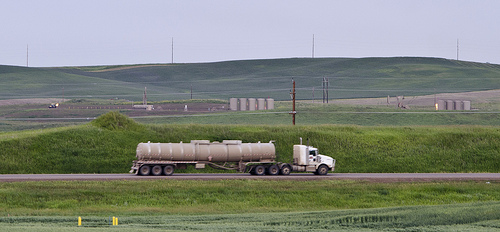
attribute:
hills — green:
[3, 55, 488, 97]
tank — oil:
[132, 136, 278, 168]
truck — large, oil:
[126, 134, 337, 179]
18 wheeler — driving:
[114, 123, 352, 190]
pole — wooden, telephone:
[291, 78, 294, 129]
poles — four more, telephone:
[6, 16, 497, 82]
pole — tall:
[308, 30, 315, 57]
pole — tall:
[454, 37, 460, 60]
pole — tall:
[169, 35, 174, 63]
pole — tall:
[24, 42, 31, 67]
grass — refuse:
[95, 182, 445, 230]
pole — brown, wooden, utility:
[271, 78, 305, 138]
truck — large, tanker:
[127, 129, 357, 190]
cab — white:
[288, 144, 338, 178]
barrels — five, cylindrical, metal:
[228, 94, 275, 113]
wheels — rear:
[135, 161, 186, 178]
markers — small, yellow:
[75, 215, 119, 227]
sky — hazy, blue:
[2, 0, 497, 70]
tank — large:
[132, 104, 289, 172]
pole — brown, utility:
[289, 75, 301, 124]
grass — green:
[5, 189, 484, 209]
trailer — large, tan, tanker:
[97, 117, 288, 199]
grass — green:
[2, 181, 497, 230]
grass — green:
[3, 118, 498, 174]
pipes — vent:
[190, 80, 280, 115]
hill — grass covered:
[71, 55, 488, 107]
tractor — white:
[289, 133, 347, 193]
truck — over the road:
[127, 126, 378, 182]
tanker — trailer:
[108, 140, 368, 171]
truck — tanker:
[129, 130, 360, 208]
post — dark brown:
[287, 71, 305, 134]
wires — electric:
[299, 74, 482, 97]